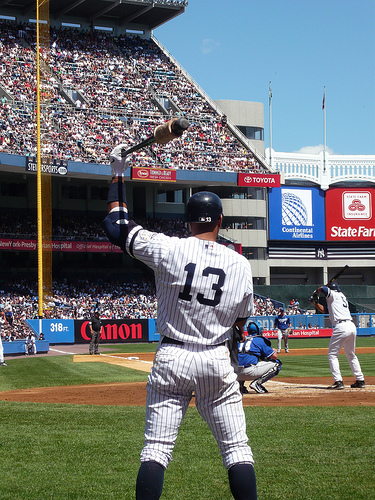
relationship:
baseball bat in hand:
[118, 119, 188, 155] [109, 143, 132, 178]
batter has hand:
[103, 143, 256, 499] [109, 143, 132, 178]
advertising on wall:
[77, 304, 141, 350] [33, 311, 372, 361]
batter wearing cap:
[103, 143, 256, 499] [185, 191, 224, 224]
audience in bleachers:
[0, 29, 272, 175] [0, 0, 280, 188]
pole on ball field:
[32, 0, 47, 319] [2, 318, 374, 497]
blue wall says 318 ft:
[25, 318, 164, 342] [48, 320, 67, 333]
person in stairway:
[76, 100, 81, 110] [61, 88, 92, 109]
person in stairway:
[81, 99, 86, 109] [61, 88, 92, 109]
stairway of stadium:
[61, 88, 92, 109] [1, 0, 374, 499]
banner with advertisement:
[233, 168, 286, 193] [247, 172, 277, 187]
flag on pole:
[321, 86, 325, 110] [321, 81, 325, 184]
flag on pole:
[268, 77, 274, 103] [265, 80, 273, 165]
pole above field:
[321, 81, 325, 184] [1, 332, 374, 488]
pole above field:
[265, 80, 273, 165] [1, 332, 374, 488]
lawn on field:
[3, 334, 373, 499] [1, 322, 373, 498]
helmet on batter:
[174, 189, 254, 240] [101, 143, 255, 498]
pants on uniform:
[132, 339, 265, 498] [117, 235, 264, 499]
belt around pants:
[159, 334, 229, 347] [132, 339, 265, 498]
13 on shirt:
[177, 260, 226, 308] [104, 207, 256, 348]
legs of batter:
[135, 343, 262, 499] [103, 143, 256, 499]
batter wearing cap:
[103, 143, 256, 499] [179, 188, 230, 243]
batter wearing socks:
[103, 143, 256, 499] [123, 445, 268, 498]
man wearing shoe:
[311, 284, 367, 388] [299, 375, 373, 391]